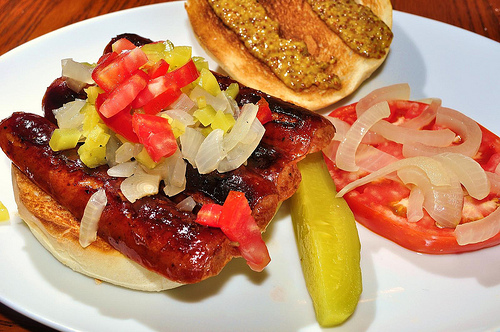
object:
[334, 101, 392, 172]
onions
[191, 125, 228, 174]
onions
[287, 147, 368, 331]
pickle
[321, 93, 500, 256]
tomato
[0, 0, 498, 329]
plate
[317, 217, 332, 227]
seeds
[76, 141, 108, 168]
peppers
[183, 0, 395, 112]
bread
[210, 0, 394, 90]
sauce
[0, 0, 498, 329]
food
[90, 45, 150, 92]
tomato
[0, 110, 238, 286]
sausage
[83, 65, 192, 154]
vegetables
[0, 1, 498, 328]
table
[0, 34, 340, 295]
sadwich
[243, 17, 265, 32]
mustard